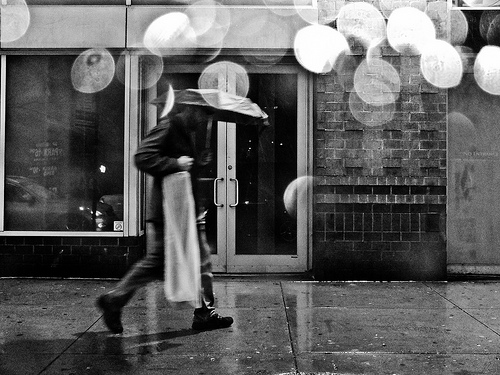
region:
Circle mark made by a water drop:
[293, 28, 353, 74]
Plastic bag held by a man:
[160, 170, 205, 313]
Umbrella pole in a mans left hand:
[201, 115, 214, 165]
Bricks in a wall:
[321, 125, 436, 167]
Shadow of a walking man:
[5, 322, 166, 371]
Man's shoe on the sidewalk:
[191, 312, 239, 336]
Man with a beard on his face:
[183, 104, 209, 132]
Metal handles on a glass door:
[210, 175, 241, 210]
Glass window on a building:
[0, 47, 130, 242]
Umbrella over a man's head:
[148, 86, 280, 128]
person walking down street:
[71, 30, 331, 371]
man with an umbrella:
[96, 30, 288, 322]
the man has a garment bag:
[64, 26, 298, 351]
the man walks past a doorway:
[91, 29, 368, 342]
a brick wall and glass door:
[237, 30, 382, 251]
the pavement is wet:
[271, 301, 424, 366]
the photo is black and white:
[42, 16, 494, 367]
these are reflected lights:
[281, 26, 436, 136]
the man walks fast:
[43, 34, 341, 354]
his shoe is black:
[154, 294, 286, 367]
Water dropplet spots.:
[20, 1, 497, 117]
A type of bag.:
[160, 156, 207, 323]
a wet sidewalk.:
[7, 276, 490, 368]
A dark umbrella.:
[141, 72, 277, 136]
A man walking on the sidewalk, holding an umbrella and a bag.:
[114, 57, 220, 371]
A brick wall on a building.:
[313, 61, 447, 267]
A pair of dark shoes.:
[74, 274, 244, 330]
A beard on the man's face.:
[179, 105, 209, 128]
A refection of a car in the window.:
[6, 164, 120, 251]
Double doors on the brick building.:
[120, 51, 330, 268]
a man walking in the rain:
[87, 81, 270, 342]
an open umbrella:
[149, 81, 276, 130]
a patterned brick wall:
[306, 55, 450, 287]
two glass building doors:
[137, 56, 311, 274]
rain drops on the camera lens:
[138, 4, 498, 123]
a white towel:
[159, 166, 208, 308]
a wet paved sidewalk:
[0, 277, 498, 373]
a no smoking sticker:
[107, 217, 127, 236]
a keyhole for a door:
[223, 162, 233, 173]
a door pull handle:
[224, 175, 241, 210]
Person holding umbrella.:
[181, 78, 276, 190]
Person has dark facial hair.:
[185, 106, 207, 144]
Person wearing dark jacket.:
[145, 129, 194, 208]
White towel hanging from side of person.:
[143, 179, 235, 339]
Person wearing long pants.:
[125, 231, 182, 308]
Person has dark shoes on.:
[96, 292, 145, 366]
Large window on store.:
[31, 118, 98, 219]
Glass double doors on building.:
[174, 92, 274, 272]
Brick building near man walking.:
[346, 149, 385, 244]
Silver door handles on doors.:
[211, 166, 252, 234]